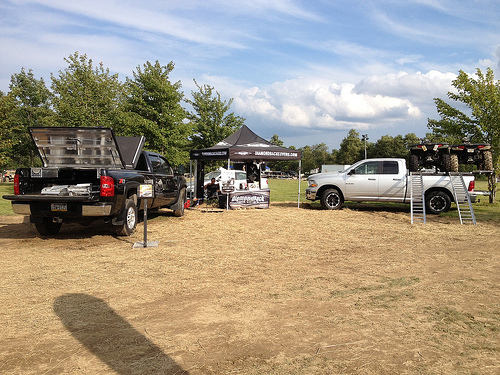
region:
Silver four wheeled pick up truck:
[305, 147, 482, 212]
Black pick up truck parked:
[20, 120, 180, 231]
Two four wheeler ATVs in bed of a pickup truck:
[397, 135, 488, 180]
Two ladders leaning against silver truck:
[401, 170, 476, 225]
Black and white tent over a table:
[177, 117, 307, 213]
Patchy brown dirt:
[169, 234, 404, 325]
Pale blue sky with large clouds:
[236, 16, 411, 133]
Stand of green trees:
[37, 67, 194, 128]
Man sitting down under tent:
[200, 142, 221, 202]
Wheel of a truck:
[318, 182, 342, 207]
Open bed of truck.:
[31, 127, 125, 170]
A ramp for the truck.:
[411, 171, 470, 226]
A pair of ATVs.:
[401, 131, 497, 174]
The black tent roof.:
[189, 119, 300, 159]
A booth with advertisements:
[217, 185, 269, 211]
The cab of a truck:
[307, 148, 408, 209]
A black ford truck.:
[26, 119, 188, 234]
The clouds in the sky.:
[246, 70, 418, 127]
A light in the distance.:
[356, 130, 371, 164]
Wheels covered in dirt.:
[448, 150, 492, 175]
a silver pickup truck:
[308, 145, 485, 225]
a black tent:
[187, 110, 302, 211]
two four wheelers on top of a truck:
[403, 135, 496, 175]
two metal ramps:
[402, 164, 486, 236]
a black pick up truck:
[13, 128, 185, 244]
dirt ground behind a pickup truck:
[12, 220, 495, 371]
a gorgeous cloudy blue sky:
[6, 2, 494, 140]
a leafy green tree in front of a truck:
[128, 63, 187, 172]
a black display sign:
[128, 179, 162, 249]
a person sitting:
[201, 174, 222, 207]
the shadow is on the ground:
[21, 280, 185, 356]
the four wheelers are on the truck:
[409, 130, 497, 190]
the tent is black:
[190, 122, 309, 169]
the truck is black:
[15, 131, 197, 222]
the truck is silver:
[304, 144, 469, 217]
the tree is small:
[132, 57, 188, 132]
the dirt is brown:
[216, 232, 317, 314]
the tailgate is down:
[473, 185, 493, 202]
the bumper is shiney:
[8, 201, 115, 228]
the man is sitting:
[202, 166, 224, 208]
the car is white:
[318, 114, 484, 273]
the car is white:
[330, 90, 463, 305]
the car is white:
[238, 73, 495, 288]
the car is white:
[282, 136, 470, 273]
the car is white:
[275, 61, 492, 252]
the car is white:
[308, 101, 452, 272]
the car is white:
[250, 96, 474, 251]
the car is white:
[259, 100, 452, 300]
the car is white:
[307, 101, 448, 282]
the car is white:
[276, 125, 486, 262]